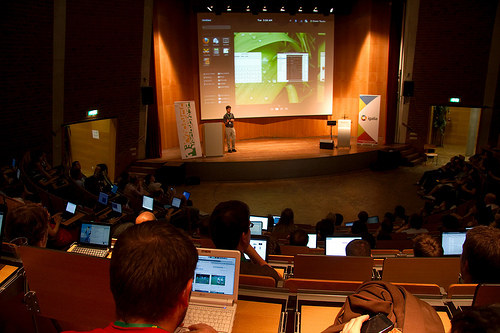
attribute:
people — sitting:
[117, 171, 163, 194]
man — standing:
[218, 104, 241, 154]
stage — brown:
[267, 143, 297, 162]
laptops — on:
[70, 214, 120, 261]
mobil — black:
[347, 314, 417, 332]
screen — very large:
[196, 10, 334, 122]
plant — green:
[429, 101, 455, 150]